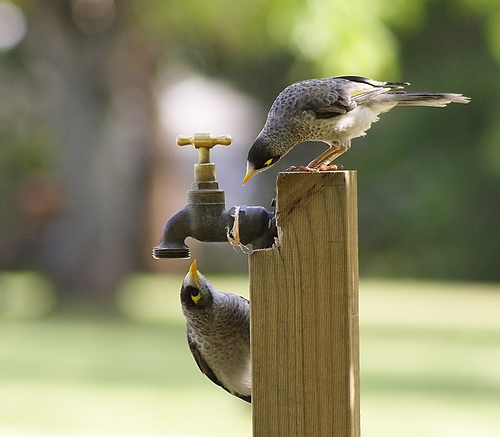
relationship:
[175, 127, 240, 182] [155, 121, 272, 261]
handle of faucet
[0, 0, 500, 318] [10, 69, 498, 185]
background on background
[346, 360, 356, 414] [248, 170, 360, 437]
light on post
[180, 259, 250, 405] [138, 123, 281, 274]
bird looking up at faucet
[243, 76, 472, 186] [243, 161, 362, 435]
bird on top of post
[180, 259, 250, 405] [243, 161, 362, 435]
bird on top of post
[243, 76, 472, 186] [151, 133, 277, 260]
bird sitting on faucet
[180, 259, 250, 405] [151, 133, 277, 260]
bird sitting on faucet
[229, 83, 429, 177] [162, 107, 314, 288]
bird looking into faucet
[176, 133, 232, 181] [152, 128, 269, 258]
handle on faucet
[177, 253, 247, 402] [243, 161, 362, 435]
bird on top post